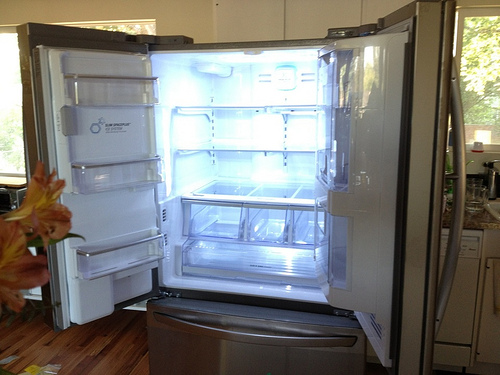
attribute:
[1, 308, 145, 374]
floor — wooden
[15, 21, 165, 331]
door — open, upper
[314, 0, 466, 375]
door — open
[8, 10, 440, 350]
refrigerator — empty, open 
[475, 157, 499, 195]
cannister — silver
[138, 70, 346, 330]
shelves — plastic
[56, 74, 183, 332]
drawers — see through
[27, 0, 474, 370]
freezer refrigirator — closed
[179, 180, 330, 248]
boxes — plastic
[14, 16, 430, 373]
doors — upper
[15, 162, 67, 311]
flower petals — yellow, orange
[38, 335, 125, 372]
floors — hardwood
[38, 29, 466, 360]
fridge — stainless steel, empty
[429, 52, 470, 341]
handle — Stainless steel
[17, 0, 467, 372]
refrigerator — brand new, empty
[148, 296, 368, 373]
freezer — lower, closed